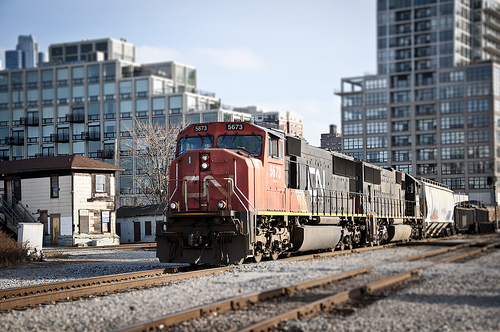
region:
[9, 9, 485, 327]
a train in an urban area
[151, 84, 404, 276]
the engine car is red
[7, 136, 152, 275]
this might be a station house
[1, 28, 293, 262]
building in the background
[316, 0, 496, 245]
some type of structure behind the train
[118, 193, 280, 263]
a small white structure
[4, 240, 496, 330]
lots of gravel on the ground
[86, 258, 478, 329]
the track is old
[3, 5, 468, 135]
the sky looks clear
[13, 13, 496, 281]
it is a sunny day over the track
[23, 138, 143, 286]
the house is white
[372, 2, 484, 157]
tall building in background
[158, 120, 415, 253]
red and black engine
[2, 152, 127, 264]
dilapidated house with brown roof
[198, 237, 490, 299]
rusty train tracks beside train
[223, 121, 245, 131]
5673 on top of train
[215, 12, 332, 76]
blue and white sky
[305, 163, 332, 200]
cn on side of train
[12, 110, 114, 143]
balconies on side of building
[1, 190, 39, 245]
staircase on side of house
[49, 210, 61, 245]
wooden door to house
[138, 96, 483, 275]
train on the train tracks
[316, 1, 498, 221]
building with a lot of windows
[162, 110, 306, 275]
front of the train is painted red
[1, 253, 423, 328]
two sets of train tracks running parallel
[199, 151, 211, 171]
two little lights on the front of the trian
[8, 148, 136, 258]
small cream colored house with a brown roof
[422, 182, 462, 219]
light reflecting on one of the train cars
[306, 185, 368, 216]
black iron railing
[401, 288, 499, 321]
shadow on the gravel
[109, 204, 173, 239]
little white building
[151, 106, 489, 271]
train going through a city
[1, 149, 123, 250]
white house with brown roof near train tracks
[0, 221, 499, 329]
layer of gravel underneath train tracks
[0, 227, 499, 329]
brown metal train tracks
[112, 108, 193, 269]
leafless tree growing near train tracks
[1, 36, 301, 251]
large office building near train tracks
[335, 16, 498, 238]
large office building overlooking train tracks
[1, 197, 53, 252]
stairs going into white house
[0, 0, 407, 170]
light blue sky with a few wispy clouds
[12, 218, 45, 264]
white box near train tracks